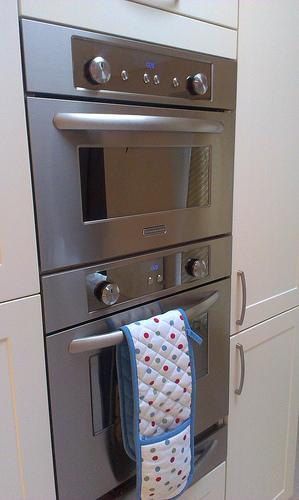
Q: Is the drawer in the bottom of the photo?
A: Yes, the drawer is in the bottom of the image.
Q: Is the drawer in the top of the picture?
A: No, the drawer is in the bottom of the image.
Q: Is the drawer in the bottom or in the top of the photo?
A: The drawer is in the bottom of the image.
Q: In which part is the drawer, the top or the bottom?
A: The drawer is in the bottom of the image.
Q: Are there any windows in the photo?
A: Yes, there is a window.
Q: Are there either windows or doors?
A: Yes, there is a window.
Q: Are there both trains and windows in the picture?
A: No, there is a window but no trains.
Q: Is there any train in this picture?
A: No, there are no trains.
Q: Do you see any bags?
A: No, there are no bags.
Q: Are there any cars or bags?
A: No, there are no bags or cars.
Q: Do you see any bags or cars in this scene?
A: No, there are no bags or cars.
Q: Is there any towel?
A: Yes, there is a towel.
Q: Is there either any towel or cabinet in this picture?
A: Yes, there is a towel.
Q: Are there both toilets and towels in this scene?
A: No, there is a towel but no toilets.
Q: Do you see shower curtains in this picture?
A: No, there are no shower curtains.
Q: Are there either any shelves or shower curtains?
A: No, there are no shower curtains or shelves.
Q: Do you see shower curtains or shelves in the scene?
A: No, there are no shower curtains or shelves.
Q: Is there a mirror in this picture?
A: No, there are no mirrors.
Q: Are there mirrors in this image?
A: No, there are no mirrors.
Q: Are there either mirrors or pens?
A: No, there are no mirrors or pens.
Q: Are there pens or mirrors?
A: No, there are no mirrors or pens.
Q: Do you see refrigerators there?
A: No, there are no refrigerators.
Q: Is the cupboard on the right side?
A: Yes, the cupboard is on the right of the image.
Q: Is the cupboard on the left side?
A: No, the cupboard is on the right of the image.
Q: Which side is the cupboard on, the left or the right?
A: The cupboard is on the right of the image.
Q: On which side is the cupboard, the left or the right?
A: The cupboard is on the right of the image.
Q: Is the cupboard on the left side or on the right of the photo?
A: The cupboard is on the right of the image.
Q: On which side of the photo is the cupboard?
A: The cupboard is on the right of the image.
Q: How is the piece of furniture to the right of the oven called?
A: The piece of furniture is a cupboard.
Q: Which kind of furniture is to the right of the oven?
A: The piece of furniture is a cupboard.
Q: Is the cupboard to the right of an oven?
A: Yes, the cupboard is to the right of an oven.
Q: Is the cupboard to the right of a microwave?
A: No, the cupboard is to the right of an oven.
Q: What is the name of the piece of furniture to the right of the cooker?
A: The piece of furniture is a cupboard.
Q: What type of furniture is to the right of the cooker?
A: The piece of furniture is a cupboard.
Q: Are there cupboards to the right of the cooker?
A: Yes, there is a cupboard to the right of the cooker.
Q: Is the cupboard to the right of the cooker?
A: Yes, the cupboard is to the right of the cooker.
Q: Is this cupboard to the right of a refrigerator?
A: No, the cupboard is to the right of the cooker.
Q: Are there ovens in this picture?
A: Yes, there is an oven.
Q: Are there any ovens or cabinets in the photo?
A: Yes, there is an oven.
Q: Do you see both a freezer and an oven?
A: No, there is an oven but no refrigerators.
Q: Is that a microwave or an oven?
A: That is an oven.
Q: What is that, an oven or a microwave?
A: That is an oven.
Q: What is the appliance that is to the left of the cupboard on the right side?
A: The appliance is an oven.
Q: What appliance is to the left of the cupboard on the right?
A: The appliance is an oven.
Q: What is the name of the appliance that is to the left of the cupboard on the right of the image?
A: The appliance is an oven.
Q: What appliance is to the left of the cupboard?
A: The appliance is an oven.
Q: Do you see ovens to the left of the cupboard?
A: Yes, there is an oven to the left of the cupboard.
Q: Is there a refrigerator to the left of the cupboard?
A: No, there is an oven to the left of the cupboard.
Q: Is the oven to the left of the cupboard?
A: Yes, the oven is to the left of the cupboard.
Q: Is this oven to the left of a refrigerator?
A: No, the oven is to the left of the cupboard.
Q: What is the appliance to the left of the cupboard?
A: The appliance is a cooker.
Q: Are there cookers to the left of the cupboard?
A: Yes, there is a cooker to the left of the cupboard.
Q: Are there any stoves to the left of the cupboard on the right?
A: No, there is a cooker to the left of the cupboard.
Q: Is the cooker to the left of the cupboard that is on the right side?
A: Yes, the cooker is to the left of the cupboard.